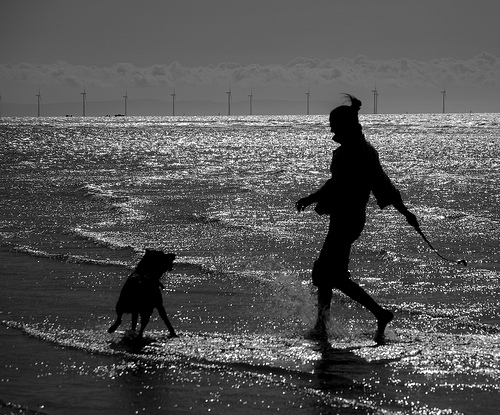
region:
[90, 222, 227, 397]
the dog is wet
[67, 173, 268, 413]
the dog is wet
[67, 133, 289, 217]
water of an ocean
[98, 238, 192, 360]
dog at a beach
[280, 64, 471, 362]
female at a beach with dog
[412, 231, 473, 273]
leash of a dog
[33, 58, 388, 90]
clouds in the sky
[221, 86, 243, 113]
windmills in the distance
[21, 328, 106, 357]
wave rolling in from ocean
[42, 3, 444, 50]
sky in the distance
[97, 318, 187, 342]
legs of a dog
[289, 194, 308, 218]
left hand of a woman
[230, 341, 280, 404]
the water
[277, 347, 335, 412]
the water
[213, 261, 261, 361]
the water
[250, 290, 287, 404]
the water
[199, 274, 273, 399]
the water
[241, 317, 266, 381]
the water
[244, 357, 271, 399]
the water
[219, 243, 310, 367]
the water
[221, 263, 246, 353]
the water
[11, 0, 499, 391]
the photo is black and white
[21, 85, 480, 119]
the wind turbines in the background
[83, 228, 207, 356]
the dog on the beach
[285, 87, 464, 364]
the woman on the beach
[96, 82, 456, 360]
the dog and woman playing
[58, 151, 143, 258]
the waves on the water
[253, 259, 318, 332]
water splashing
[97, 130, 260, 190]
the ocean is calm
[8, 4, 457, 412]
the wind is blowing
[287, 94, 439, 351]
a woman playing with a dog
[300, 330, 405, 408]
the shadow of a woman on the water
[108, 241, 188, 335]
a dog playing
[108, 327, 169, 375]
the shadow of a dog on the water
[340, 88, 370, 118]
a pony tail blowing in the wind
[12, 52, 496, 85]
a line of clouds in the sky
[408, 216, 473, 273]
a toy in a woman's hand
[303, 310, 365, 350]
a foot kicking up water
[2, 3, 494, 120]
a gray night sky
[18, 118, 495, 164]
light reflecting of the water